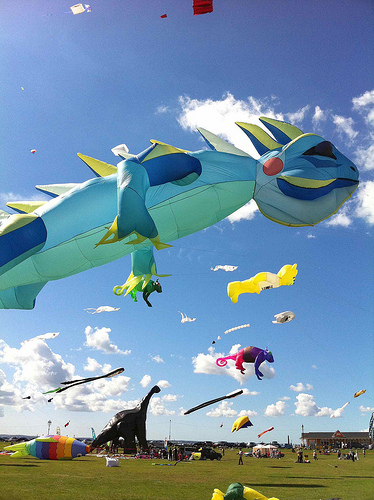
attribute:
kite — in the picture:
[213, 307, 297, 350]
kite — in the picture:
[271, 308, 293, 323]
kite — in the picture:
[351, 386, 367, 397]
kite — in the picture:
[224, 261, 300, 303]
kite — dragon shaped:
[1, 112, 360, 307]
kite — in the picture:
[253, 424, 278, 441]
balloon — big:
[97, 116, 362, 242]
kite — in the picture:
[230, 416, 251, 433]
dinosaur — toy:
[1, 117, 358, 309]